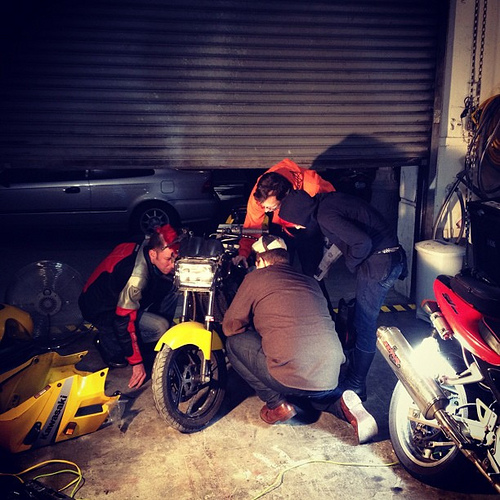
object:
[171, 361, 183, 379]
spoke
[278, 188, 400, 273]
jacket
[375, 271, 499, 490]
motorcycle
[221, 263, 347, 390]
shirt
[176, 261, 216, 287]
headlight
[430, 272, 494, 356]
red seat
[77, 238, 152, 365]
jacket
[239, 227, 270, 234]
handlebar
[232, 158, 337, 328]
man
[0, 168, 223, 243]
car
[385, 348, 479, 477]
wheel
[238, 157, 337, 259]
red jacket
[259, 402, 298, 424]
shoe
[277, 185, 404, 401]
man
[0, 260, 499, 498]
ground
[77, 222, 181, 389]
man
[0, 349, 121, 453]
part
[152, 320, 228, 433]
wheel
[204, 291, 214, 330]
cycle shocks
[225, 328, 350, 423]
pants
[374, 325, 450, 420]
muffler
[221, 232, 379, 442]
man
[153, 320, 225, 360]
frame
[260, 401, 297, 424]
foot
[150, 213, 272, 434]
motorbike